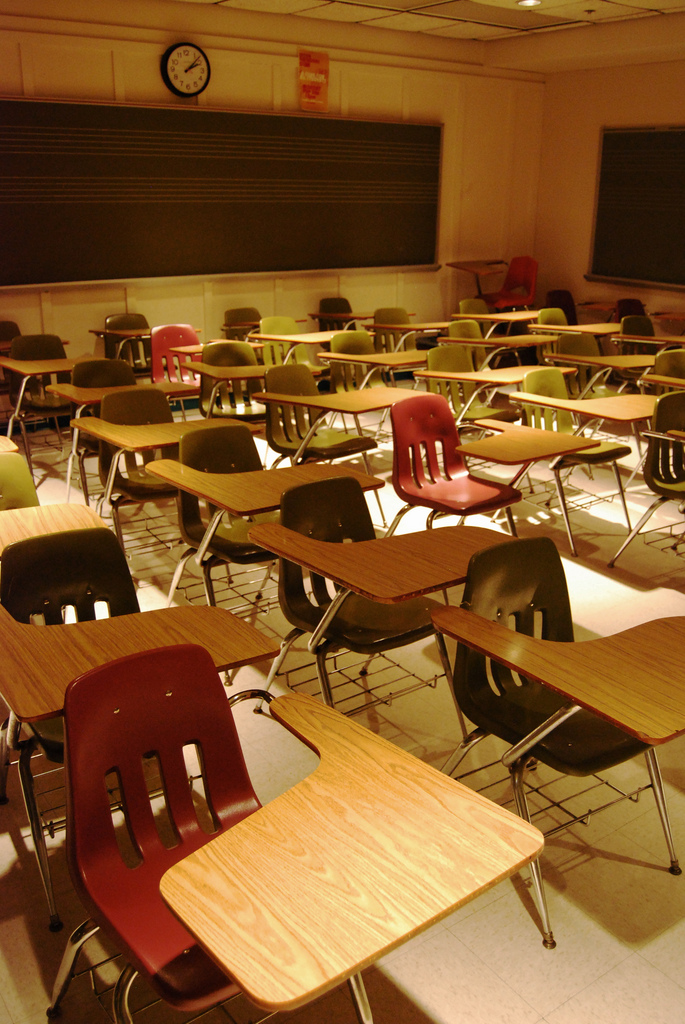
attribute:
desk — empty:
[240, 518, 511, 747]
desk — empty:
[139, 441, 386, 625]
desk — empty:
[61, 410, 268, 565]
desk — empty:
[249, 382, 445, 528]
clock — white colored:
[156, 39, 212, 99]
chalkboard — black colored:
[3, 90, 448, 300]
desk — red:
[453, 401, 579, 487]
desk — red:
[251, 384, 461, 411]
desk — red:
[256, 314, 347, 363]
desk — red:
[37, 360, 155, 419]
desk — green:
[510, 367, 640, 470]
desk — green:
[90, 386, 225, 468]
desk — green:
[518, 355, 642, 540]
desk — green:
[411, 528, 682, 844]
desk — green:
[356, 294, 448, 398]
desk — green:
[241, 302, 343, 416]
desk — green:
[253, 466, 475, 722]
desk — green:
[253, 464, 480, 684]